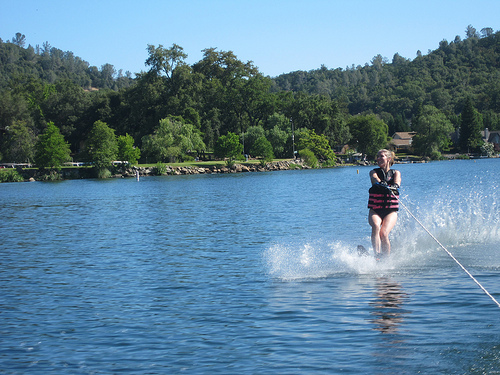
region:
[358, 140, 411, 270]
A woman water skiing on the lake.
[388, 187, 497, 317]
A water skiiing tether line.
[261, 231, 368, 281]
The water splashes up in the wake of the skiier.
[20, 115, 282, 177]
Small trees along the shoreline.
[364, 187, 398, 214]
A life vest with pink stripes.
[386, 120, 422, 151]
A house, obscured by trees.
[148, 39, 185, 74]
A tall tree stands above the rest.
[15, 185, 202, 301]
Cool blue water on the placid lake.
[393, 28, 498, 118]
A mountain dotted with trees.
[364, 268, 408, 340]
The reflection of the woman in the water.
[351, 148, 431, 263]
Woman water skiing.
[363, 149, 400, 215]
Woman wearing red and black life vest.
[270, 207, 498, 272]
Water splashing up from water skis.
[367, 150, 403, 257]
Woman wearing black bathing suit.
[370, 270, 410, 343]
Reflection of woman on water.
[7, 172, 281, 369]
Beautiful blue lake.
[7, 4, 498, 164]
Tall green trees surrounding lake.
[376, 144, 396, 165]
Woman's blond hair.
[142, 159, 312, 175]
Rocks along edge of water.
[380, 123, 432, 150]
Houses surrounded by trees.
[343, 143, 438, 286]
a lady is water skiing on a lake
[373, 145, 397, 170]
the girl has her hair in a bun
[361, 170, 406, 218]
a red and black life vest is on the woman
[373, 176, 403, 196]
the lady is wearing black gloves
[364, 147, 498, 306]
the lady is holding the ski rope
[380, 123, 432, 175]
a house is on the lakeside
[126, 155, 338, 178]
boulders are on the river bank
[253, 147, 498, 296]
the lady is making the water splash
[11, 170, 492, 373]
the water is calm with ripples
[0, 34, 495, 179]
mountains and trees surround the lake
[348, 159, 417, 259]
the woman is surfing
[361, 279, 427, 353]
reflection is in the water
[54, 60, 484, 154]
the forest is green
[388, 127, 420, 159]
houses are in the background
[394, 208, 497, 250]
water is splashing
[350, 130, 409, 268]
she is smilling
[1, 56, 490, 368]
it is daylight outside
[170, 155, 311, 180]
rocks are on the riverside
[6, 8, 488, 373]
the scene is outdoors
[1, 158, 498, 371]
the water is very blue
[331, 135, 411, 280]
Girl riding a ski in the water.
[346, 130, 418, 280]
Girl in the water.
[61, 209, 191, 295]
Part of the water.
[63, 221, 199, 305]
Part of the blue water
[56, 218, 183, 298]
Part of a large body of blue water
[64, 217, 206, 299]
Part of a large body of water.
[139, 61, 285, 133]
Part of some trees.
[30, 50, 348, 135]
Part of a large group of trees.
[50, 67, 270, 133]
Part of a large group of green trees.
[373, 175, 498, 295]
Rope held by woman.